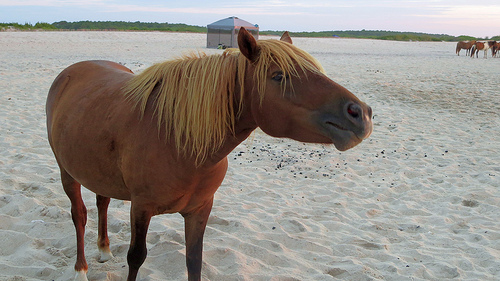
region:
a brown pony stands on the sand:
[44, 25, 377, 278]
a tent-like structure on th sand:
[203, 13, 260, 50]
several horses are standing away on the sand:
[454, 38, 498, 60]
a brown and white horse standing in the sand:
[467, 37, 497, 61]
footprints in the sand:
[1, 35, 494, 277]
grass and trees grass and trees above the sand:
[0, 20, 495, 40]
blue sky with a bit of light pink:
[375, 3, 498, 35]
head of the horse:
[230, 30, 370, 170]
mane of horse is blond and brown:
[115, 35, 325, 160]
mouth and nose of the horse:
[315, 96, 371, 143]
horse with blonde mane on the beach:
[36, 20, 389, 265]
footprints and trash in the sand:
[255, 139, 347, 220]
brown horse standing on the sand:
[32, 27, 372, 268]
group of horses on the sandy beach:
[442, 26, 499, 67]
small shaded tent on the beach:
[196, 2, 273, 70]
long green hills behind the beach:
[5, 11, 448, 51]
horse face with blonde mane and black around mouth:
[227, 20, 377, 160]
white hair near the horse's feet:
[61, 233, 119, 278]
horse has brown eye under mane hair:
[255, 65, 301, 102]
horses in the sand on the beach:
[50, 24, 496, 275]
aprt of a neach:
[323, 225, 355, 275]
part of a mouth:
[328, 100, 352, 159]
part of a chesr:
[175, 139, 237, 231]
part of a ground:
[263, 183, 284, 221]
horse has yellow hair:
[118, 38, 314, 160]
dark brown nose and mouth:
[318, 99, 375, 146]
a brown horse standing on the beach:
[48, 49, 371, 275]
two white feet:
[71, 247, 111, 279]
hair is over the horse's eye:
[271, 69, 294, 93]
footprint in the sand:
[203, 245, 238, 275]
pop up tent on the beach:
[206, 17, 259, 47]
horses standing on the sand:
[456, 38, 498, 57]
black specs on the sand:
[233, 141, 409, 173]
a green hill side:
[6, 20, 478, 40]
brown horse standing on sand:
[29, 15, 379, 277]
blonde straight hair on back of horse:
[116, 35, 326, 162]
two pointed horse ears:
[222, 18, 297, 63]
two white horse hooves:
[51, 239, 133, 278]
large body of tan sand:
[3, 28, 498, 275]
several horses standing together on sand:
[447, 33, 499, 65]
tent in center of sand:
[197, 9, 267, 56]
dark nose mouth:
[316, 108, 372, 155]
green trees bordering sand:
[1, 15, 497, 57]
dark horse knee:
[118, 245, 163, 268]